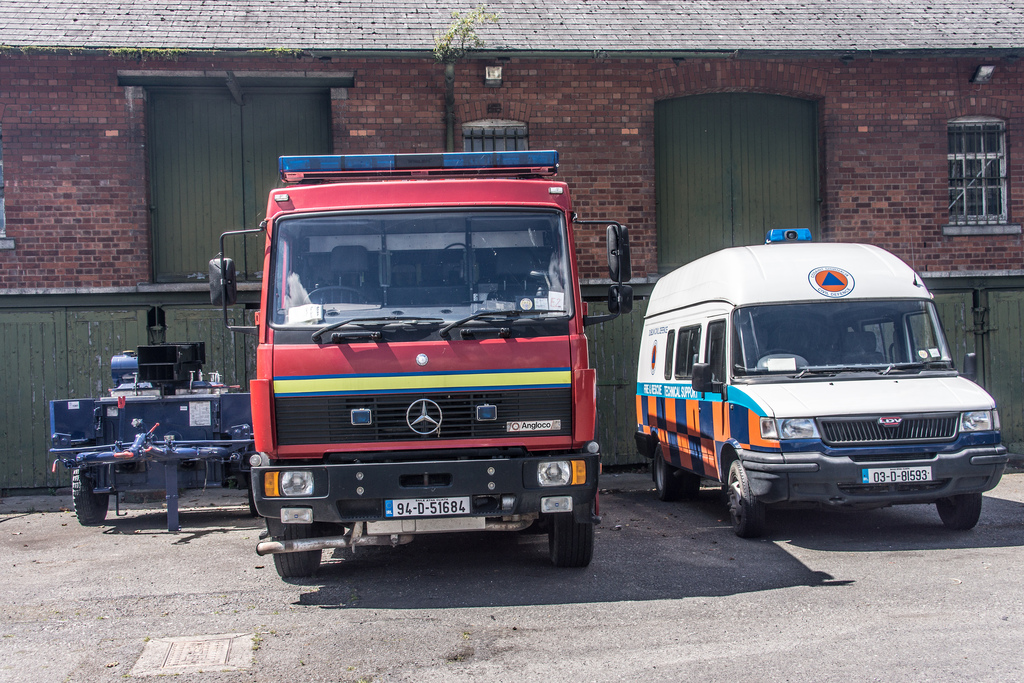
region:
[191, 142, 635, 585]
Red truck with blue lights on top of roof.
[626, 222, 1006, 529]
White blue and orange van.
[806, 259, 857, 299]
Blue triangle inside an orange and white circle.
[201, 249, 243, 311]
Large black truck side mirror.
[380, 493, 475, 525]
White license plate with black letters and numbers.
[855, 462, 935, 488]
White license plate with black letters and numbers.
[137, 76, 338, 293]
Green wooden double door.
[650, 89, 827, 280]
Green wooden double door.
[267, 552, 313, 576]
tire on the car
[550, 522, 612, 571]
tire on the car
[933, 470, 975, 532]
tire on the car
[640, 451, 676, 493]
tire on the car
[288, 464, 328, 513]
light on the car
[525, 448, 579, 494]
light on the car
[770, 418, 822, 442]
light on the car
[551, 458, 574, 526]
light on the car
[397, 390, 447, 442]
emblem on front of truck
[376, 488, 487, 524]
license plate on truck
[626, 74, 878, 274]
green doors on a building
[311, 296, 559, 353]
windshield wipers on a truck window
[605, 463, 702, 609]
shadow casted on the ground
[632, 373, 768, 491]
design on side of van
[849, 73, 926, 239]
brick facade of a building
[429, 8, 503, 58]
green leaves of weeds in gutter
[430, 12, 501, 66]
A small green grass on gutter.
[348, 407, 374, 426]
A blue square light with silver border.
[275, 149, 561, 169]
A long blue light.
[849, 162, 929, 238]
Part of a bricked wall.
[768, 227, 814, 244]
A small rectangular blue light.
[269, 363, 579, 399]
A yellow line with blue border.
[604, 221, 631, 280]
A long side mirror.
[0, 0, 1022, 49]
A gray bricked roof.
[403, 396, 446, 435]
A round stainless steel logo.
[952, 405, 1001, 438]
Right headlight of a ambulance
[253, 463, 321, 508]
Left headlight of a vehicle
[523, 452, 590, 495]
Right headlight of a vehicle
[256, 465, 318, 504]
Left headlight of a red vehicle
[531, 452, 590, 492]
Right headlight of a red vehicle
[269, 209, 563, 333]
Window of a vehicle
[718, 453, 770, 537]
Tire of a ambulance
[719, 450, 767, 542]
Black tire of a ambulance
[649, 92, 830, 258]
a large green door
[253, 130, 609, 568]
the front of a red truck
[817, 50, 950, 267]
the side of a brick building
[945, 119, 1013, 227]
a window of a building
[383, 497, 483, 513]
a long black and white license plate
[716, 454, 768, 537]
a wheel of a van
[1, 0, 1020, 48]
a roof of a building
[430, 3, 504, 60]
green tree leaves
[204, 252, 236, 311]
a long black rear view mirror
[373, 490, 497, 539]
license plate on the bus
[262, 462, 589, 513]
head lights on the bus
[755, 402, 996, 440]
head lights on the bus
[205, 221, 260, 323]
Mirror on the bus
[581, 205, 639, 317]
Mirror on the bus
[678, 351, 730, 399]
Mirror on the bus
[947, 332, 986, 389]
Mirror on the bus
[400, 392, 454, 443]
emblem on the bus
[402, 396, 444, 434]
the mercedes logo on the truck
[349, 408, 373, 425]
the blue light of the truck